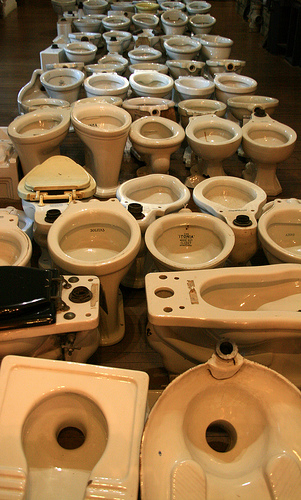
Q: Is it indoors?
A: Yes, it is indoors.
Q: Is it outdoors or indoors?
A: It is indoors.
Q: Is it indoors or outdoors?
A: It is indoors.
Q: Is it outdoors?
A: No, it is indoors.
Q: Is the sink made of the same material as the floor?
A: No, the sink is made of glass and the floor is made of wood.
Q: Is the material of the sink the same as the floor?
A: No, the sink is made of glass and the floor is made of wood.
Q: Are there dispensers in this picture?
A: No, there are no dispensers.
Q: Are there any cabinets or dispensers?
A: No, there are no dispensers or cabinets.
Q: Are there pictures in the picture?
A: No, there are no pictures.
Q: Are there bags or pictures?
A: No, there are no pictures or bags.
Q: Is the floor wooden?
A: Yes, the floor is wooden.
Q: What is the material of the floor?
A: The floor is made of wood.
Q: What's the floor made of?
A: The floor is made of wood.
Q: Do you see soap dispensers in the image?
A: No, there are no soap dispensers.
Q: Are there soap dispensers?
A: No, there are no soap dispensers.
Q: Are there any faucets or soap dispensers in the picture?
A: No, there are no soap dispensers or faucets.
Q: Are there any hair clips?
A: No, there are no hair clips.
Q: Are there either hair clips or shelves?
A: No, there are no hair clips or shelves.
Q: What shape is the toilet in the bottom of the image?
A: The toilet is square.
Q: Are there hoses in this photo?
A: No, there are no hoses.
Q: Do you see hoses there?
A: No, there are no hoses.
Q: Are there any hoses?
A: No, there are no hoses.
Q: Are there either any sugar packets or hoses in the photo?
A: No, there are no hoses or sugar packets.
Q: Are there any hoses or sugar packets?
A: No, there are no hoses or sugar packets.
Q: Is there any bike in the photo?
A: No, there are no bikes.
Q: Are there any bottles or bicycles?
A: No, there are no bicycles or bottles.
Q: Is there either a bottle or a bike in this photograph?
A: No, there are no bikes or bottles.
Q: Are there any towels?
A: No, there are no towels.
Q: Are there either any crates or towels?
A: No, there are no towels or crates.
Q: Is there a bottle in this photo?
A: No, there are no bottles.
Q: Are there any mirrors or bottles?
A: No, there are no bottles or mirrors.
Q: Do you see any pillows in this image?
A: No, there are no pillows.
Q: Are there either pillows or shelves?
A: No, there are no pillows or shelves.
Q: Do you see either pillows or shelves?
A: No, there are no pillows or shelves.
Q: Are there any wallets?
A: No, there are no wallets.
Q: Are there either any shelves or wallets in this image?
A: No, there are no wallets or shelves.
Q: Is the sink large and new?
A: Yes, the sink is large and new.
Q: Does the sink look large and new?
A: Yes, the sink is large and new.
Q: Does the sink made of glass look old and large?
A: No, the sink is large but new.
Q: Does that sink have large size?
A: Yes, the sink is large.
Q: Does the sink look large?
A: Yes, the sink is large.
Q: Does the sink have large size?
A: Yes, the sink is large.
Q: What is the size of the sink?
A: The sink is large.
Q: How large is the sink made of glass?
A: The sink is large.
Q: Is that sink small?
A: No, the sink is large.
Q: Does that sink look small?
A: No, the sink is large.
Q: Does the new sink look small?
A: No, the sink is large.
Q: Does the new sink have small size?
A: No, the sink is large.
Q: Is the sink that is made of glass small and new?
A: No, the sink is new but large.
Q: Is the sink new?
A: Yes, the sink is new.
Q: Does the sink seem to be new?
A: Yes, the sink is new.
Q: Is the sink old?
A: No, the sink is new.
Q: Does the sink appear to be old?
A: No, the sink is new.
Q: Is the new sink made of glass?
A: Yes, the sink is made of glass.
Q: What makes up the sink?
A: The sink is made of glass.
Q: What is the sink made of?
A: The sink is made of glass.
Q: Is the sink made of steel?
A: No, the sink is made of glass.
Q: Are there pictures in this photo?
A: No, there are no pictures.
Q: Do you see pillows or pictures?
A: No, there are no pictures or pillows.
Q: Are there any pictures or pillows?
A: No, there are no pictures or pillows.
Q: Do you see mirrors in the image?
A: No, there are no mirrors.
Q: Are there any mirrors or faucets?
A: No, there are no mirrors or faucets.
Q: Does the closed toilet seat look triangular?
A: Yes, the toilet seat is triangular.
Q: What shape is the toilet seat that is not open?
A: The toilet seat is triangular.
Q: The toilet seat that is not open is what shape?
A: The toilet seat is triangular.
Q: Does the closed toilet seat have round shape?
A: No, the toilet seat is triangular.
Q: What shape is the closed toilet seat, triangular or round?
A: The toilet seat is triangular.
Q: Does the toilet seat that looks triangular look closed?
A: Yes, the toilet seat is closed.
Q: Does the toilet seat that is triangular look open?
A: No, the toilet seat is closed.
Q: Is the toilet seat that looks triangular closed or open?
A: The toilet seat is closed.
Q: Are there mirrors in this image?
A: No, there are no mirrors.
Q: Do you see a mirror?
A: No, there are no mirrors.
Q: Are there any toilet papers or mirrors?
A: No, there are no mirrors or toilet papers.